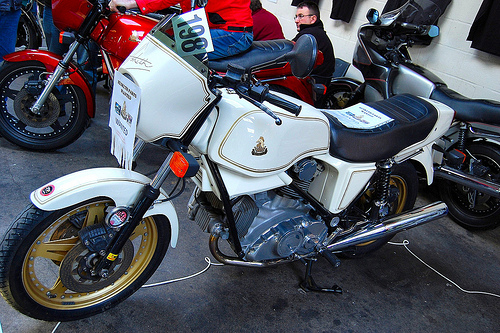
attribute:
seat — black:
[322, 87, 439, 157]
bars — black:
[141, 121, 258, 236]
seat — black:
[299, 73, 440, 178]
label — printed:
[167, 8, 222, 57]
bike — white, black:
[3, 17, 451, 323]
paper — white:
[328, 86, 383, 130]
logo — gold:
[247, 137, 284, 161]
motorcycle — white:
[0, 4, 456, 322]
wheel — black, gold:
[3, 197, 172, 322]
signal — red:
[166, 149, 201, 181]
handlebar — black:
[223, 71, 305, 124]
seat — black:
[324, 88, 433, 168]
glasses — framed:
[289, 10, 307, 20]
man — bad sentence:
[291, 4, 336, 94]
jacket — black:
[291, 20, 338, 90]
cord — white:
[138, 252, 225, 292]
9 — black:
[176, 26, 210, 38]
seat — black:
[322, 90, 437, 162]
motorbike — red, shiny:
[19, 28, 481, 315]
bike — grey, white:
[362, 23, 499, 230]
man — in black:
[282, 1, 344, 73]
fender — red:
[25, 37, 90, 126]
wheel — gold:
[21, 197, 157, 309]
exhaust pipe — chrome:
[208, 199, 448, 268]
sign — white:
[106, 69, 142, 170]